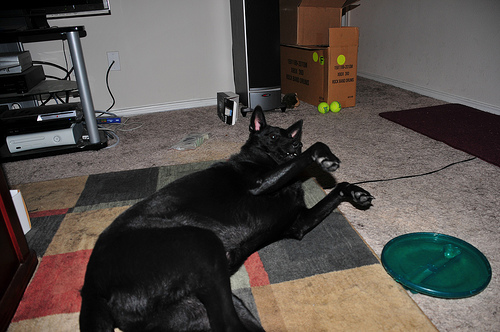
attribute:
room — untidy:
[41, 33, 382, 328]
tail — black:
[67, 288, 102, 329]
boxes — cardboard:
[275, 0, 367, 102]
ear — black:
[245, 96, 274, 138]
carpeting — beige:
[413, 184, 496, 222]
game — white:
[5, 117, 91, 153]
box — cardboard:
[279, 22, 362, 107]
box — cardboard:
[276, 40, 358, 106]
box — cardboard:
[275, 4, 345, 45]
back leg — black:
[141, 215, 246, 324]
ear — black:
[246, 105, 266, 132]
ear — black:
[286, 116, 304, 138]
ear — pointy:
[249, 106, 269, 133]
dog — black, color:
[211, 111, 334, 233]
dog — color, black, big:
[80, 108, 375, 328]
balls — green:
[316, 98, 346, 115]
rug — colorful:
[37, 164, 184, 286]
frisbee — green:
[361, 226, 482, 300]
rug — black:
[376, 101, 498, 168]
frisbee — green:
[383, 214, 498, 316]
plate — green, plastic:
[380, 230, 493, 300]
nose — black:
[275, 142, 299, 159]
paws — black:
[311, 146, 370, 207]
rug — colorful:
[0, 161, 436, 327]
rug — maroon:
[376, 98, 484, 168]